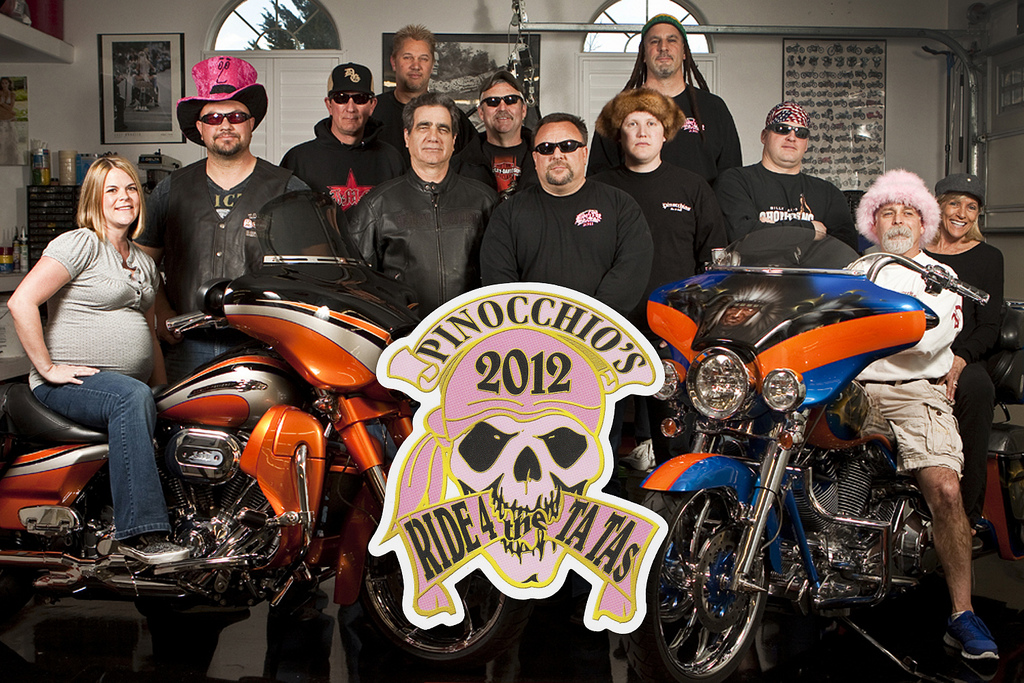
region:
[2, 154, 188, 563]
person sitting on motorcycle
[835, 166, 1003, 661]
person sitting on motorcycle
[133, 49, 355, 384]
person standing behind motorcycle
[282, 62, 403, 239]
person standing behind motorcycle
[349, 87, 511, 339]
person standing behind motorcycle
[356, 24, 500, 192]
person standing behind motorcycle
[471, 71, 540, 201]
person standing behind motorcycle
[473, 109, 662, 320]
person standing behind motorcycle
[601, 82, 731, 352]
person standing behind motorcycle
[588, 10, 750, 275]
person standing behind motorcycle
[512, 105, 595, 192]
the head of a man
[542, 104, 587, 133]
the hair of a man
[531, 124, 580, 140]
the forehead of a man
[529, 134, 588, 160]
the sunglasses of a man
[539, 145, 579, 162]
the nose of a man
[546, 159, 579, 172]
the mouth of a man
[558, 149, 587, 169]
the cheek of a man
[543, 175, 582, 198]
the neck of a man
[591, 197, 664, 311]
the left arm of a man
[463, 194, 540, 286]
the right arm of a man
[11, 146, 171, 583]
a pregnant woman siting on a motorcycle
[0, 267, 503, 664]
an orange and silver motorcycle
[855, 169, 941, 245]
a furry pink hat on a man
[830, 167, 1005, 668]
a man sitting on a motorcycle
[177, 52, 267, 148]
a red tye dye top hat on a man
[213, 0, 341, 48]
an arched window above a shuttered window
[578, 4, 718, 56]
an arched window above a shuttered window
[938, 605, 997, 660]
a blue tennis shoe on a man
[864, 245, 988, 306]
handle bar on a motorcycle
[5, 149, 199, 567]
woman wearing a gray shirt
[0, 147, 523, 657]
woman sitting on motor bike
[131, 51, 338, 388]
man wearing pink hat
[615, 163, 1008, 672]
man with pink hat sitting on motorbike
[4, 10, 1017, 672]
people in front of pink logo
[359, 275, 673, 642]
pink logo with pinocchio's written on it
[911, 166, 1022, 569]
woman wearing black cap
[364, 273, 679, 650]
logo with 2012 on it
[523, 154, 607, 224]
the mouth of a man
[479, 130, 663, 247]
the neck of a man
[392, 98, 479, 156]
the eyes of a man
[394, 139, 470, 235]
the chin of a man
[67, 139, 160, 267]
the head of a woman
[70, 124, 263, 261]
the chin of a man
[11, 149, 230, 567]
pregnant woman sitting on motorcycle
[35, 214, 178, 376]
short sleeve gray shirt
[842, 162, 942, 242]
fuzzy light pink hat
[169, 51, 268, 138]
Pink top hat on man's head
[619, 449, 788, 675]
Front wheel of motorcycle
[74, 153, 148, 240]
Woman's head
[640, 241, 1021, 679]
Blue and orange motorcycle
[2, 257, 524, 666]
Orange and white motorcycle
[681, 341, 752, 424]
front light of motorcycle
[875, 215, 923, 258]
White beard and mustache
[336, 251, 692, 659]
Skull and crossed bones sign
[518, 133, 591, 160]
sunglasses on a man's face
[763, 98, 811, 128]
American flag bandanna on a person's head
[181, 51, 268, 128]
The pink hat the man is wearing on the left.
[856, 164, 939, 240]
The pink furry hat the man is wearing.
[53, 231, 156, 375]
The shirt the pregnant woman is wearing.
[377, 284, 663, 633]
The sign in front of the people.